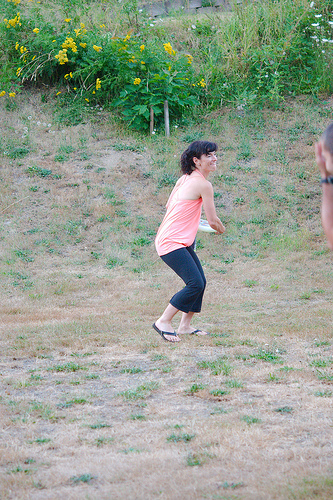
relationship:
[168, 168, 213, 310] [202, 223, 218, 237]
girl with frisbee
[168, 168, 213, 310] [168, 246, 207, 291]
girl wearing pants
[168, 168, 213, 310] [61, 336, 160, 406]
girl on grass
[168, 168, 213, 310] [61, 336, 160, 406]
girl in grass